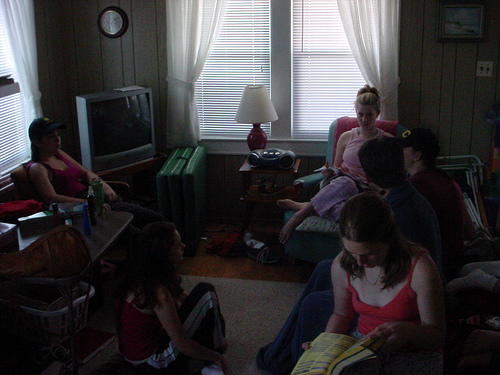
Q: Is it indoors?
A: Yes, it is indoors.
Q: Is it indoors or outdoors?
A: It is indoors.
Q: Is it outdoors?
A: No, it is indoors.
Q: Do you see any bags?
A: No, there are no bags.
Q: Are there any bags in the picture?
A: No, there are no bags.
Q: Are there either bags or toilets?
A: No, there are no bags or toilets.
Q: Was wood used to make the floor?
A: Yes, the floor is made of wood.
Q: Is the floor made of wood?
A: Yes, the floor is made of wood.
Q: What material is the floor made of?
A: The floor is made of wood.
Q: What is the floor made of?
A: The floor is made of wood.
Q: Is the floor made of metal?
A: No, the floor is made of wood.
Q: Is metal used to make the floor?
A: No, the floor is made of wood.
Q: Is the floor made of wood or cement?
A: The floor is made of wood.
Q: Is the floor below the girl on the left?
A: Yes, the floor is below the girl.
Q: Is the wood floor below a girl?
A: Yes, the floor is below a girl.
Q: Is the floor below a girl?
A: Yes, the floor is below a girl.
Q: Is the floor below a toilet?
A: No, the floor is below a girl.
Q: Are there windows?
A: Yes, there is a window.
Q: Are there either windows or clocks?
A: Yes, there is a window.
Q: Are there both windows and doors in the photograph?
A: No, there is a window but no doors.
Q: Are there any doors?
A: No, there are no doors.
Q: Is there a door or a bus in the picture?
A: No, there are no doors or buses.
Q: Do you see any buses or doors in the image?
A: No, there are no doors or buses.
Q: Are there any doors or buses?
A: No, there are no doors or buses.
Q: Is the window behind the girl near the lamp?
A: Yes, the window is behind the girl.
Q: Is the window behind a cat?
A: No, the window is behind the girl.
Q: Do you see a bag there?
A: No, there are no bags.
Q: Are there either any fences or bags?
A: No, there are no bags or fences.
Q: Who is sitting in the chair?
A: The girl is sitting in the chair.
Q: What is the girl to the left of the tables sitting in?
A: The girl is sitting in the chair.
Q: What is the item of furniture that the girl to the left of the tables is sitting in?
A: The piece of furniture is a chair.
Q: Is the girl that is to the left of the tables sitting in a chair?
A: Yes, the girl is sitting in a chair.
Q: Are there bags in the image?
A: No, there are no bags.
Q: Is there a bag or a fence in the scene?
A: No, there are no bags or fences.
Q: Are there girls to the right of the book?
A: No, the girl is to the left of the book.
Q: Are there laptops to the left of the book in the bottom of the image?
A: No, there is a girl to the left of the book.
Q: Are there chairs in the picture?
A: Yes, there is a chair.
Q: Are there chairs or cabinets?
A: Yes, there is a chair.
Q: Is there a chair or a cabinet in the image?
A: Yes, there is a chair.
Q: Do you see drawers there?
A: No, there are no drawers.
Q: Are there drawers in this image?
A: No, there are no drawers.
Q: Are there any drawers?
A: No, there are no drawers.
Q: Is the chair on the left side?
A: Yes, the chair is on the left of the image.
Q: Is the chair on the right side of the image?
A: No, the chair is on the left of the image.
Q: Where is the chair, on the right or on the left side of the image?
A: The chair is on the left of the image.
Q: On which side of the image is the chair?
A: The chair is on the left of the image.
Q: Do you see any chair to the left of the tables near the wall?
A: Yes, there is a chair to the left of the tables.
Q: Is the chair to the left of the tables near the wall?
A: Yes, the chair is to the left of the tables.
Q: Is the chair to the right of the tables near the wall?
A: No, the chair is to the left of the tables.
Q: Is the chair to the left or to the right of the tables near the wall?
A: The chair is to the left of the tables.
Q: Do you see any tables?
A: Yes, there is a table.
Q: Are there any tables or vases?
A: Yes, there is a table.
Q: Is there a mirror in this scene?
A: No, there are no mirrors.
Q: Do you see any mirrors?
A: No, there are no mirrors.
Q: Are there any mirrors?
A: No, there are no mirrors.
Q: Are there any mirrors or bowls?
A: No, there are no mirrors or bowls.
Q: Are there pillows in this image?
A: No, there are no pillows.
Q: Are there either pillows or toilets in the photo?
A: No, there are no pillows or toilets.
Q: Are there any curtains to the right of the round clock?
A: Yes, there is a curtain to the right of the clock.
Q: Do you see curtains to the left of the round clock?
A: No, the curtain is to the right of the clock.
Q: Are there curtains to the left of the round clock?
A: No, the curtain is to the right of the clock.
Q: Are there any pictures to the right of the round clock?
A: No, there is a curtain to the right of the clock.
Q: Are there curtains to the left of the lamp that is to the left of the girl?
A: Yes, there is a curtain to the left of the lamp.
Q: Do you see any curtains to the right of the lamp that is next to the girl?
A: No, the curtain is to the left of the lamp.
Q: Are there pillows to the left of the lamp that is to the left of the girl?
A: No, there is a curtain to the left of the lamp.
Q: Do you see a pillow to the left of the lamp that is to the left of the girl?
A: No, there is a curtain to the left of the lamp.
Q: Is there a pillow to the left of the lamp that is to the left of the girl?
A: No, there is a curtain to the left of the lamp.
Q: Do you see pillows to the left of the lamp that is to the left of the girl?
A: No, there is a curtain to the left of the lamp.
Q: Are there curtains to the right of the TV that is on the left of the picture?
A: Yes, there is a curtain to the right of the TV.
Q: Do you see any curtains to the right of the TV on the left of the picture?
A: Yes, there is a curtain to the right of the TV.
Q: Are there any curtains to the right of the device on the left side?
A: Yes, there is a curtain to the right of the TV.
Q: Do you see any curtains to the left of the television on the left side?
A: No, the curtain is to the right of the television.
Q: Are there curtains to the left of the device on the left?
A: No, the curtain is to the right of the television.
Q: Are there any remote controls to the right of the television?
A: No, there is a curtain to the right of the television.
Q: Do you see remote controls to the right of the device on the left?
A: No, there is a curtain to the right of the television.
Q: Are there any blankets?
A: No, there are no blankets.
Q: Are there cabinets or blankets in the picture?
A: No, there are no blankets or cabinets.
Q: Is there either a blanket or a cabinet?
A: No, there are no blankets or cabinets.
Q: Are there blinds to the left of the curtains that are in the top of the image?
A: Yes, there are blinds to the left of the curtains.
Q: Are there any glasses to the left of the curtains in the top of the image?
A: No, there are blinds to the left of the curtains.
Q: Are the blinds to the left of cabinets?
A: No, the blinds are to the left of the curtains.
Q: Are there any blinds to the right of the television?
A: Yes, there are blinds to the right of the television.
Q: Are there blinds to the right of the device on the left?
A: Yes, there are blinds to the right of the television.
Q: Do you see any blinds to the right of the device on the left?
A: Yes, there are blinds to the right of the television.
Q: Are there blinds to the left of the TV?
A: No, the blinds are to the right of the TV.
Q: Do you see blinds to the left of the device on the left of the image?
A: No, the blinds are to the right of the TV.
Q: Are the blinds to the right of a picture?
A: No, the blinds are to the right of a television.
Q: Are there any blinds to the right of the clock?
A: Yes, there are blinds to the right of the clock.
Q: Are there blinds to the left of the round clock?
A: No, the blinds are to the right of the clock.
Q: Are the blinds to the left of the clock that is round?
A: No, the blinds are to the right of the clock.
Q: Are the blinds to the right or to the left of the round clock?
A: The blinds are to the right of the clock.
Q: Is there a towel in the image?
A: No, there are no towels.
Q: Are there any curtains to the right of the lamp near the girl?
A: Yes, there are curtains to the right of the lamp.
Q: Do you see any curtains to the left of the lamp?
A: No, the curtains are to the right of the lamp.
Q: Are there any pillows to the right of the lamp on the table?
A: No, there are curtains to the right of the lamp.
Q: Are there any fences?
A: No, there are no fences.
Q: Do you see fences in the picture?
A: No, there are no fences.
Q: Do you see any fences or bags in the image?
A: No, there are no fences or bags.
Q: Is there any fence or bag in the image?
A: No, there are no fences or bags.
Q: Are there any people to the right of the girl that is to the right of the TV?
A: Yes, there are people to the right of the girl.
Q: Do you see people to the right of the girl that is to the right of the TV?
A: Yes, there are people to the right of the girl.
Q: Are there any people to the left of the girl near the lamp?
A: No, the people are to the right of the girl.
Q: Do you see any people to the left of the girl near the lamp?
A: No, the people are to the right of the girl.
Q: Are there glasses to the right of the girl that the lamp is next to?
A: No, there are people to the right of the girl.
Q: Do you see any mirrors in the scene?
A: No, there are no mirrors.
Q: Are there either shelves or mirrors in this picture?
A: No, there are no mirrors or shelves.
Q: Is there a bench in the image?
A: No, there are no benches.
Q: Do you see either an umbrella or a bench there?
A: No, there are no benches or umbrellas.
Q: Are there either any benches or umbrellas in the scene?
A: No, there are no benches or umbrellas.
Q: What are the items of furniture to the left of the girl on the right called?
A: The pieces of furniture are tables.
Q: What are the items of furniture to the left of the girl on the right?
A: The pieces of furniture are tables.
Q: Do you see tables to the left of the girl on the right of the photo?
A: Yes, there are tables to the left of the girl.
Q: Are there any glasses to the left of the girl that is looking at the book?
A: No, there are tables to the left of the girl.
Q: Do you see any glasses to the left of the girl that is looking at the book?
A: No, there are tables to the left of the girl.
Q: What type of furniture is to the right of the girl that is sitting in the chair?
A: The pieces of furniture are tables.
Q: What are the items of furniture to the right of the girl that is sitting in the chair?
A: The pieces of furniture are tables.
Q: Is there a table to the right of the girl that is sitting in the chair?
A: Yes, there are tables to the right of the girl.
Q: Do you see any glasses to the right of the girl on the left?
A: No, there are tables to the right of the girl.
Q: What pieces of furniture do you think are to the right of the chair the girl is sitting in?
A: The pieces of furniture are tables.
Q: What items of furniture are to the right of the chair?
A: The pieces of furniture are tables.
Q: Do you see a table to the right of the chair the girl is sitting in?
A: Yes, there are tables to the right of the chair.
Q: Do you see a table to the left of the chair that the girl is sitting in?
A: No, the tables are to the right of the chair.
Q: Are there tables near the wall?
A: Yes, there are tables near the wall.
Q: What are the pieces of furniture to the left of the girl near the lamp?
A: The pieces of furniture are tables.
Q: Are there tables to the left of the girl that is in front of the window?
A: Yes, there are tables to the left of the girl.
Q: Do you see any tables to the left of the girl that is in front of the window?
A: Yes, there are tables to the left of the girl.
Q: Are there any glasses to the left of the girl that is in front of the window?
A: No, there are tables to the left of the girl.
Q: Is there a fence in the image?
A: No, there are no fences.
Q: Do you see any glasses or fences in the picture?
A: No, there are no fences or glasses.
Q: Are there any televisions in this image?
A: Yes, there is a television.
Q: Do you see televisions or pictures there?
A: Yes, there is a television.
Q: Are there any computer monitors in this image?
A: No, there are no computer monitors.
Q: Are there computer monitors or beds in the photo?
A: No, there are no computer monitors or beds.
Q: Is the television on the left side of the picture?
A: Yes, the television is on the left of the image.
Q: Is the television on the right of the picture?
A: No, the television is on the left of the image.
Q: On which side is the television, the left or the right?
A: The television is on the left of the image.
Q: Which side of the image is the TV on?
A: The TV is on the left of the image.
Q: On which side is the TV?
A: The TV is on the left of the image.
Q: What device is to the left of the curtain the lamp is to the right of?
A: The device is a television.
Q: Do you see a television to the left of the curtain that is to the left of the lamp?
A: Yes, there is a television to the left of the curtain.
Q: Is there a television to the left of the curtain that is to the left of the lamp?
A: Yes, there is a television to the left of the curtain.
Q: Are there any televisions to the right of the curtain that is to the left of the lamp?
A: No, the television is to the left of the curtain.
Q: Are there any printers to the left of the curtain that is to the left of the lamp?
A: No, there is a television to the left of the curtain.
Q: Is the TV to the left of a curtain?
A: Yes, the TV is to the left of a curtain.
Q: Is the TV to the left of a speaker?
A: No, the TV is to the left of a curtain.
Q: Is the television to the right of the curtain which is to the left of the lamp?
A: No, the television is to the left of the curtain.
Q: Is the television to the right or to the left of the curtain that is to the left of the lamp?
A: The television is to the left of the curtain.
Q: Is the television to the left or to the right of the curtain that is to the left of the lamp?
A: The television is to the left of the curtain.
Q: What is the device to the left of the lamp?
A: The device is a television.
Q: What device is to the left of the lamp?
A: The device is a television.